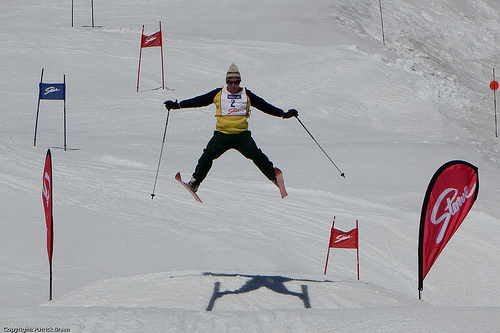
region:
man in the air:
[146, 66, 321, 222]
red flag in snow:
[398, 145, 485, 301]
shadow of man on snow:
[185, 245, 336, 326]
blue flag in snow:
[23, 63, 84, 153]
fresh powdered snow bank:
[220, 18, 370, 58]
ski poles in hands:
[283, 101, 363, 187]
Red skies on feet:
[170, 170, 300, 205]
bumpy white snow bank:
[391, 25, 468, 103]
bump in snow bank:
[107, 296, 382, 326]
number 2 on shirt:
[213, 92, 268, 112]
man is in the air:
[150, 50, 357, 235]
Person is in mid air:
[143, 47, 358, 238]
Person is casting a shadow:
[150, 239, 358, 321]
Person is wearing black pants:
[175, 123, 290, 205]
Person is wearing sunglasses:
[185, 51, 266, 96]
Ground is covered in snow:
[45, 55, 416, 281]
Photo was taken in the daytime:
[24, 23, 461, 303]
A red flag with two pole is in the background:
[125, 20, 175, 92]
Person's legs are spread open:
[146, 136, 327, 223]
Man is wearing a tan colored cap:
[205, 62, 257, 101]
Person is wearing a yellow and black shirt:
[167, 73, 299, 145]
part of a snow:
[352, 85, 410, 131]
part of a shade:
[259, 261, 291, 306]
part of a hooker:
[331, 162, 356, 182]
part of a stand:
[351, 249, 368, 277]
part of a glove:
[283, 102, 297, 122]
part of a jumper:
[228, 126, 243, 139]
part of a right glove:
[159, 90, 174, 115]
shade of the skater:
[243, 258, 288, 318]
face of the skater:
[226, 64, 238, 94]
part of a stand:
[361, 5, 401, 42]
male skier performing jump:
[168, 50, 342, 217]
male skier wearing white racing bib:
[206, 87, 261, 126]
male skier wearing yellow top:
[201, 88, 256, 138]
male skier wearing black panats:
[183, 126, 271, 177]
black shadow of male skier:
[193, 255, 315, 318]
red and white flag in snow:
[318, 200, 373, 292]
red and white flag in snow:
[400, 143, 489, 307]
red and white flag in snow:
[31, 148, 82, 310]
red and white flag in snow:
[122, 15, 179, 90]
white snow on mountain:
[341, 40, 452, 155]